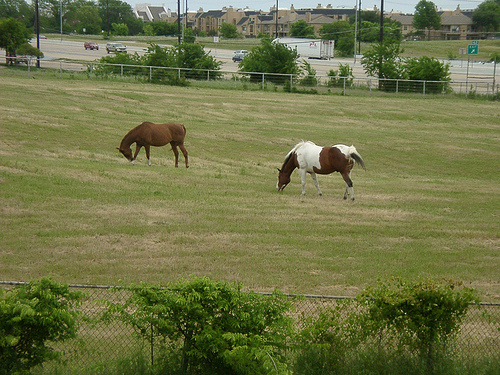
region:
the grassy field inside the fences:
[4, 64, 498, 300]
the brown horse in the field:
[113, 118, 185, 163]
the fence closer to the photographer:
[0, 275, 495, 370]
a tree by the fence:
[125, 280, 290, 370]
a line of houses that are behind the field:
[181, 8, 482, 44]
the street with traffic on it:
[43, 42, 495, 86]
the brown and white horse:
[268, 135, 365, 202]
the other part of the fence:
[1, 55, 498, 104]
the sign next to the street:
[466, 41, 480, 53]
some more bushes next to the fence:
[106, 48, 211, 78]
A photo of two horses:
[17, 47, 451, 328]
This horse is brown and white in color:
[269, 126, 375, 209]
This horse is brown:
[109, 119, 199, 170]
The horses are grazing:
[94, 94, 403, 224]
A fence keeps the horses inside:
[8, 256, 494, 371]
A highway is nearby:
[61, 30, 345, 82]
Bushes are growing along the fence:
[14, 302, 449, 365]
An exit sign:
[461, 37, 488, 63]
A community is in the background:
[151, 5, 480, 37]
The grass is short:
[114, 182, 260, 265]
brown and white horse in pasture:
[266, 134, 371, 209]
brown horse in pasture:
[108, 117, 197, 177]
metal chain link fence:
[57, 277, 169, 374]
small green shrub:
[347, 274, 477, 374]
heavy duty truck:
[266, 36, 338, 61]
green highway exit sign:
[453, 39, 485, 66]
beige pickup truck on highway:
[102, 41, 129, 56]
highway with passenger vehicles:
[39, 36, 151, 68]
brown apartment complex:
[165, 11, 338, 41]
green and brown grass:
[0, 142, 117, 209]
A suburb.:
[125, 3, 485, 55]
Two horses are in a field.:
[22, 40, 457, 257]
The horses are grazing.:
[70, 85, 380, 235]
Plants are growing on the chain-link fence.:
[5, 270, 497, 365]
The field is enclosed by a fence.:
[0, 45, 495, 355]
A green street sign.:
[452, 31, 482, 77]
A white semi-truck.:
[261, 22, 336, 69]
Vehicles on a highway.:
[20, 11, 497, 91]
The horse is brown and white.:
[245, 127, 365, 202]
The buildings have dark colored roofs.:
[192, 5, 478, 45]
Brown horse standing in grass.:
[91, 96, 228, 230]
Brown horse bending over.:
[95, 111, 197, 172]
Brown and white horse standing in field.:
[258, 133, 423, 239]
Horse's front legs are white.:
[292, 161, 330, 226]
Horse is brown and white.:
[258, 102, 403, 239]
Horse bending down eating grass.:
[265, 170, 324, 249]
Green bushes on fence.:
[48, 285, 488, 356]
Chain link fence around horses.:
[91, 260, 425, 355]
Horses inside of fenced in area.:
[21, 67, 420, 288]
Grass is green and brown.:
[43, 69, 428, 281]